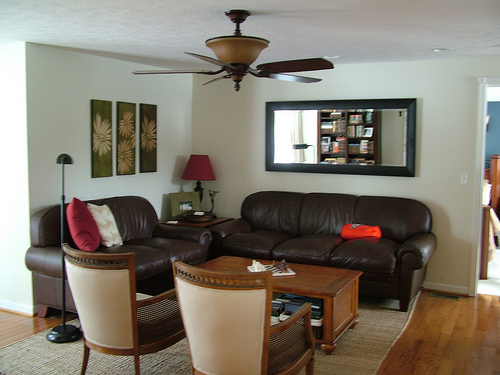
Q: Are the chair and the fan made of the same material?
A: Yes, both the chair and the fan are made of wood.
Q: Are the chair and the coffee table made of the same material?
A: Yes, both the chair and the coffee table are made of wood.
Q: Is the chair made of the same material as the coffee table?
A: Yes, both the chair and the coffee table are made of wood.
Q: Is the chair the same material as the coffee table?
A: Yes, both the chair and the coffee table are made of wood.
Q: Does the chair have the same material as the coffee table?
A: Yes, both the chair and the coffee table are made of wood.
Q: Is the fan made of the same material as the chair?
A: Yes, both the fan and the chair are made of wood.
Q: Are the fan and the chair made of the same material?
A: Yes, both the fan and the chair are made of wood.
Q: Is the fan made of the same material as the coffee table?
A: Yes, both the fan and the coffee table are made of wood.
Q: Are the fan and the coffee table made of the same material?
A: Yes, both the fan and the coffee table are made of wood.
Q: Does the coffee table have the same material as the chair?
A: Yes, both the coffee table and the chair are made of wood.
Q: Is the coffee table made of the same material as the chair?
A: Yes, both the coffee table and the chair are made of wood.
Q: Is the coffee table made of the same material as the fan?
A: Yes, both the coffee table and the fan are made of wood.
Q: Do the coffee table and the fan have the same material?
A: Yes, both the coffee table and the fan are made of wood.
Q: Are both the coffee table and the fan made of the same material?
A: Yes, both the coffee table and the fan are made of wood.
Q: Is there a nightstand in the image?
A: Yes, there is a nightstand.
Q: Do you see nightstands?
A: Yes, there is a nightstand.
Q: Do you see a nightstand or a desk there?
A: Yes, there is a nightstand.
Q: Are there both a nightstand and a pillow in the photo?
A: Yes, there are both a nightstand and a pillow.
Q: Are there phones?
A: No, there are no phones.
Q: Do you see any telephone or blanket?
A: No, there are no phones or blankets.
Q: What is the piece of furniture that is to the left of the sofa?
A: The piece of furniture is a nightstand.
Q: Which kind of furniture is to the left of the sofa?
A: The piece of furniture is a nightstand.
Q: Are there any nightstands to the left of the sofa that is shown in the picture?
A: Yes, there is a nightstand to the left of the sofa.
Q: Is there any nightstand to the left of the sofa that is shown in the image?
A: Yes, there is a nightstand to the left of the sofa.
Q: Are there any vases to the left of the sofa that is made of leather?
A: No, there is a nightstand to the left of the sofa.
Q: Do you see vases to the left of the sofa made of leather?
A: No, there is a nightstand to the left of the sofa.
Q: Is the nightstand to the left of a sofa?
A: Yes, the nightstand is to the left of a sofa.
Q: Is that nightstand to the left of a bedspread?
A: No, the nightstand is to the left of a sofa.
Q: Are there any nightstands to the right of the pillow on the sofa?
A: Yes, there is a nightstand to the right of the pillow.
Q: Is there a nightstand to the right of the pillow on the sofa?
A: Yes, there is a nightstand to the right of the pillow.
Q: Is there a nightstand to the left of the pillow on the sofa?
A: No, the nightstand is to the right of the pillow.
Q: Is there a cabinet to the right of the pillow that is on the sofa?
A: No, there is a nightstand to the right of the pillow.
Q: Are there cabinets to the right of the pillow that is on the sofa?
A: No, there is a nightstand to the right of the pillow.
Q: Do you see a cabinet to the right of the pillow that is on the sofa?
A: No, there is a nightstand to the right of the pillow.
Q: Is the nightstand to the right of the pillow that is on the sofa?
A: Yes, the nightstand is to the right of the pillow.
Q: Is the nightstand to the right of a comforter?
A: No, the nightstand is to the right of the pillow.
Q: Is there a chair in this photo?
A: Yes, there is a chair.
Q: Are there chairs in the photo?
A: Yes, there is a chair.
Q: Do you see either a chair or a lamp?
A: Yes, there is a chair.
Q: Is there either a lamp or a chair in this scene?
A: Yes, there is a chair.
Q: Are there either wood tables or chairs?
A: Yes, there is a wood chair.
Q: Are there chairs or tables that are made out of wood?
A: Yes, the chair is made of wood.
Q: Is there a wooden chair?
A: Yes, there is a wood chair.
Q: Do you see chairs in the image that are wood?
A: Yes, there is a wood chair.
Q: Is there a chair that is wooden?
A: Yes, there is a chair that is wooden.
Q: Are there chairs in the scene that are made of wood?
A: Yes, there is a chair that is made of wood.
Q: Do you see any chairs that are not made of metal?
A: Yes, there is a chair that is made of wood.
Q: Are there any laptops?
A: No, there are no laptops.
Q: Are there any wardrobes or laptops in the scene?
A: No, there are no laptops or wardrobes.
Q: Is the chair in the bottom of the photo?
A: Yes, the chair is in the bottom of the image.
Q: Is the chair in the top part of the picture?
A: No, the chair is in the bottom of the image.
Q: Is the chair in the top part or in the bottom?
A: The chair is in the bottom of the image.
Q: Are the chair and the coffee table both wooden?
A: Yes, both the chair and the coffee table are wooden.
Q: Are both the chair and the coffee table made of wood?
A: Yes, both the chair and the coffee table are made of wood.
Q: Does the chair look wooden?
A: Yes, the chair is wooden.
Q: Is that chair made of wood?
A: Yes, the chair is made of wood.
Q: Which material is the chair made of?
A: The chair is made of wood.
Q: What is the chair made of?
A: The chair is made of wood.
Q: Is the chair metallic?
A: No, the chair is wooden.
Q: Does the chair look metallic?
A: No, the chair is wooden.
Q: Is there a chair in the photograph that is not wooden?
A: No, there is a chair but it is wooden.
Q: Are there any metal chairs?
A: No, there is a chair but it is made of wood.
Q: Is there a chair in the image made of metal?
A: No, there is a chair but it is made of wood.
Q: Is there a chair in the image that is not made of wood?
A: No, there is a chair but it is made of wood.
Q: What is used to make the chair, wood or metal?
A: The chair is made of wood.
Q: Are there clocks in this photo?
A: No, there are no clocks.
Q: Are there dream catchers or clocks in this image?
A: No, there are no clocks or dream catchers.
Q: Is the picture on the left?
A: Yes, the picture is on the left of the image.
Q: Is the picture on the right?
A: No, the picture is on the left of the image.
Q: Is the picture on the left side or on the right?
A: The picture is on the left of the image.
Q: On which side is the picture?
A: The picture is on the left of the image.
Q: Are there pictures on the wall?
A: Yes, there is a picture on the wall.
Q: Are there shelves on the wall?
A: No, there is a picture on the wall.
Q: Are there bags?
A: Yes, there is a bag.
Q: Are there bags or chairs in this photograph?
A: Yes, there is a bag.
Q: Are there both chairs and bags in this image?
A: Yes, there are both a bag and a chair.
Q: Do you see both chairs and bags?
A: Yes, there are both a bag and a chair.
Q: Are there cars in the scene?
A: No, there are no cars.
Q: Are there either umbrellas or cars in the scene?
A: No, there are no cars or umbrellas.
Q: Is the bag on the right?
A: Yes, the bag is on the right of the image.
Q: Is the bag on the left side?
A: No, the bag is on the right of the image.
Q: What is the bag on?
A: The bag is on the sofa.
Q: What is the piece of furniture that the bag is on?
A: The piece of furniture is a sofa.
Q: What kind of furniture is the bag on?
A: The bag is on the sofa.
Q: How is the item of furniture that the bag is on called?
A: The piece of furniture is a sofa.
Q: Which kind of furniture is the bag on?
A: The bag is on the sofa.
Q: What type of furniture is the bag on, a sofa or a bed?
A: The bag is on a sofa.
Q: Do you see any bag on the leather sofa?
A: Yes, there is a bag on the sofa.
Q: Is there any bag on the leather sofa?
A: Yes, there is a bag on the sofa.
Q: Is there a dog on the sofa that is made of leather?
A: No, there is a bag on the sofa.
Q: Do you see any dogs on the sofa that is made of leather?
A: No, there is a bag on the sofa.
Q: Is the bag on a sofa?
A: Yes, the bag is on a sofa.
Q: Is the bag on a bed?
A: No, the bag is on a sofa.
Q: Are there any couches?
A: Yes, there is a couch.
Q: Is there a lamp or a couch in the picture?
A: Yes, there is a couch.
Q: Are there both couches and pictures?
A: Yes, there are both a couch and a picture.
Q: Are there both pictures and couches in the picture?
A: Yes, there are both a couch and a picture.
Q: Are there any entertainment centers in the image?
A: No, there are no entertainment centers.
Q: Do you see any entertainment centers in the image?
A: No, there are no entertainment centers.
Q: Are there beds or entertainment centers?
A: No, there are no entertainment centers or beds.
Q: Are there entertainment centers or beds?
A: No, there are no entertainment centers or beds.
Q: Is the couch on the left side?
A: Yes, the couch is on the left of the image.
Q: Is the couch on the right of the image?
A: No, the couch is on the left of the image.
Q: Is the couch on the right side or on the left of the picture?
A: The couch is on the left of the image.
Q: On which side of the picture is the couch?
A: The couch is on the left of the image.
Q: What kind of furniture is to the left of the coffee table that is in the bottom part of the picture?
A: The piece of furniture is a couch.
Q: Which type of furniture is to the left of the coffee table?
A: The piece of furniture is a couch.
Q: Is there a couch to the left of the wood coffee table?
A: Yes, there is a couch to the left of the coffee table.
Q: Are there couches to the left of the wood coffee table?
A: Yes, there is a couch to the left of the coffee table.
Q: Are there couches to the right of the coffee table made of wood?
A: No, the couch is to the left of the coffee table.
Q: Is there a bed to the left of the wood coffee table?
A: No, there is a couch to the left of the coffee table.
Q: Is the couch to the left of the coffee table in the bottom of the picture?
A: Yes, the couch is to the left of the coffee table.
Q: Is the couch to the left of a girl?
A: No, the couch is to the left of the coffee table.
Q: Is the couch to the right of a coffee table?
A: No, the couch is to the left of a coffee table.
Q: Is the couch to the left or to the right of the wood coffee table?
A: The couch is to the left of the coffee table.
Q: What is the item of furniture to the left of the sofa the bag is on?
A: The piece of furniture is a couch.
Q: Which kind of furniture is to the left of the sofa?
A: The piece of furniture is a couch.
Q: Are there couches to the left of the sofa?
A: Yes, there is a couch to the left of the sofa.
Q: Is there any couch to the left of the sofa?
A: Yes, there is a couch to the left of the sofa.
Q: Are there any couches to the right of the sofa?
A: No, the couch is to the left of the sofa.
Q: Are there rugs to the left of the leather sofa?
A: No, there is a couch to the left of the sofa.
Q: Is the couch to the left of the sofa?
A: Yes, the couch is to the left of the sofa.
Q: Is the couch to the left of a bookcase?
A: No, the couch is to the left of the sofa.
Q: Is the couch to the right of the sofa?
A: No, the couch is to the left of the sofa.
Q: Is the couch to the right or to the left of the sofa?
A: The couch is to the left of the sofa.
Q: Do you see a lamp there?
A: Yes, there is a lamp.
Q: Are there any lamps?
A: Yes, there is a lamp.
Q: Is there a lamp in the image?
A: Yes, there is a lamp.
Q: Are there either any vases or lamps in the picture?
A: Yes, there is a lamp.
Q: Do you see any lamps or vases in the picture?
A: Yes, there is a lamp.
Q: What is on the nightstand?
A: The lamp is on the nightstand.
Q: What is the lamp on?
A: The lamp is on the nightstand.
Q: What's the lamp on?
A: The lamp is on the nightstand.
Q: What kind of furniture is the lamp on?
A: The lamp is on the nightstand.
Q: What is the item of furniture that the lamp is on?
A: The piece of furniture is a nightstand.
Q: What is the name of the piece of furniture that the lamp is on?
A: The piece of furniture is a nightstand.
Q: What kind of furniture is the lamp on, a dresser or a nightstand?
A: The lamp is on a nightstand.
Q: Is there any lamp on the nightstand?
A: Yes, there is a lamp on the nightstand.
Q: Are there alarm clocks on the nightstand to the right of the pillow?
A: No, there is a lamp on the nightstand.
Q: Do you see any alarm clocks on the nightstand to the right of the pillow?
A: No, there is a lamp on the nightstand.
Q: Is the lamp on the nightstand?
A: Yes, the lamp is on the nightstand.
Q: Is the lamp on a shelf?
A: No, the lamp is on the nightstand.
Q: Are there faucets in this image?
A: No, there are no faucets.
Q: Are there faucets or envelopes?
A: No, there are no faucets or envelopes.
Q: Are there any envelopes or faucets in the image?
A: No, there are no faucets or envelopes.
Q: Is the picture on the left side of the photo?
A: Yes, the picture is on the left of the image.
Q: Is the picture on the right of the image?
A: No, the picture is on the left of the image.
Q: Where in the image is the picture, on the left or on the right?
A: The picture is on the left of the image.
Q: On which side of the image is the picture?
A: The picture is on the left of the image.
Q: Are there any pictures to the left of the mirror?
A: Yes, there is a picture to the left of the mirror.